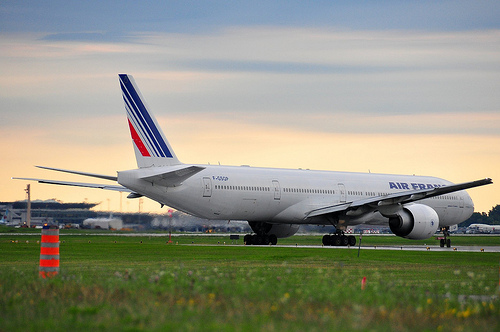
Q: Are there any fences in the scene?
A: No, there are no fences.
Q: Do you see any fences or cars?
A: No, there are no fences or cars.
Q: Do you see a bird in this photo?
A: No, there are no birds.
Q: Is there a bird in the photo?
A: No, there are no birds.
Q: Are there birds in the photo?
A: No, there are no birds.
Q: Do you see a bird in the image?
A: No, there are no birds.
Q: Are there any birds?
A: No, there are no birds.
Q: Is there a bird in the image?
A: No, there are no birds.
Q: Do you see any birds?
A: No, there are no birds.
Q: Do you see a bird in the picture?
A: No, there are no birds.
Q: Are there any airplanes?
A: Yes, there is an airplane.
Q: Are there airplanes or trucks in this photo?
A: Yes, there is an airplane.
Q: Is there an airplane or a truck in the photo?
A: Yes, there is an airplane.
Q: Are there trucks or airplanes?
A: Yes, there is an airplane.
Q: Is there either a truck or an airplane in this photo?
A: Yes, there is an airplane.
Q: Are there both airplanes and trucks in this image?
A: No, there is an airplane but no trucks.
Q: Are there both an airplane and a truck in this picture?
A: No, there is an airplane but no trucks.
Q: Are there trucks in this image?
A: No, there are no trucks.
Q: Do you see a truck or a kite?
A: No, there are no trucks or kites.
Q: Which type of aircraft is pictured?
A: The aircraft is an airplane.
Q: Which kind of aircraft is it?
A: The aircraft is an airplane.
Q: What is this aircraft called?
A: This is an airplane.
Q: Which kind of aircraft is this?
A: This is an airplane.